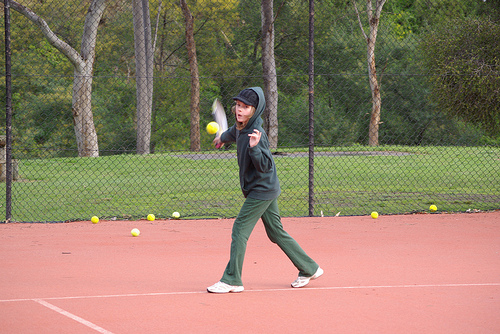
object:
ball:
[371, 211, 378, 218]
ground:
[0, 212, 499, 334]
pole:
[308, 0, 315, 218]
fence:
[0, 0, 499, 222]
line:
[32, 298, 115, 334]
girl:
[207, 86, 324, 293]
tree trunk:
[362, 36, 380, 147]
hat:
[233, 89, 259, 109]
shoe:
[207, 281, 244, 293]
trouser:
[219, 196, 319, 285]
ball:
[206, 121, 219, 134]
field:
[0, 145, 499, 224]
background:
[0, 0, 500, 223]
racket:
[210, 97, 229, 149]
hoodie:
[220, 86, 281, 201]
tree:
[1, 0, 117, 158]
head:
[230, 87, 265, 123]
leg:
[221, 193, 277, 285]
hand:
[248, 129, 262, 149]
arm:
[249, 128, 274, 174]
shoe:
[291, 265, 324, 287]